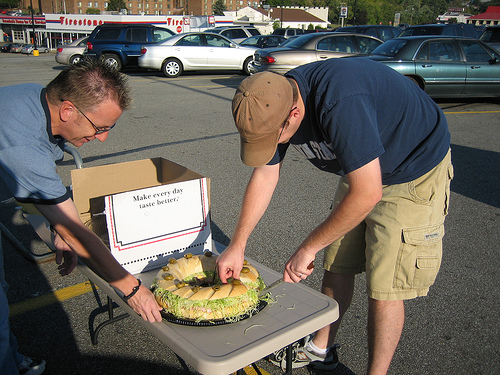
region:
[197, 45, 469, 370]
Man cutting a sandwich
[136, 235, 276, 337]
Sandwich of bread and salad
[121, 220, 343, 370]
Sandwich on a folded table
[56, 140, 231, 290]
Box of cardboard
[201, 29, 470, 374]
Man wears a blue t-shirt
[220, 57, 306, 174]
Brown cap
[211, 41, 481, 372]
Man wears tan short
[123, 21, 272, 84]
White car parking on street parking lot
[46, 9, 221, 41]
Store of Firestone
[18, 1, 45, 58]
Pole with yellow base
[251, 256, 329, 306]
knife in a persons hand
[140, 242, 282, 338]
food on a table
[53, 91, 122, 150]
glasses on a persons face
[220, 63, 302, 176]
hat on a persons head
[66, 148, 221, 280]
cardboard box on a table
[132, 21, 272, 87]
vehicle in a lot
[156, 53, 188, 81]
rear wheel of a vehicle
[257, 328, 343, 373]
shoe on a foot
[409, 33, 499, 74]
side windows on a vehicle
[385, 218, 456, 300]
pocket on a persons shorts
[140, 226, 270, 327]
A sandwich shaped like a ring.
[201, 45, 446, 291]
The man is wearing cargo shorts.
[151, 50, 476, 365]
The man is cutting the sandwich.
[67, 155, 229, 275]
A cardboard box.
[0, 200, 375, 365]
A folding table.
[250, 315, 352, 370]
A gray New Balance sneaker.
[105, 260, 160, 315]
A bracelet is on the man's arm.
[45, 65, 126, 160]
The man is wearing glasses.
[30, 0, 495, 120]
A parking lot.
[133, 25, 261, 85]
A silver car.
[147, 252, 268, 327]
Donut shaped sandwich on a black plate.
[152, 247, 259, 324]
Large wheel shaped sandwich.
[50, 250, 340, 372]
Large deli sandwich with lettuce.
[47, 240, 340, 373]
Deli sandwich on a table.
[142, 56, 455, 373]
Man cutting a large deli sandwich.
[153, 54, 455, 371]
Man standing in a parking lot cutting a large sandwich.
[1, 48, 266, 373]
Man wearing glasses in blue shirt.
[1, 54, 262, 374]
Man holding a the black tray with a large deli sandwich.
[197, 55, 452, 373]
Man wearing a brown cap.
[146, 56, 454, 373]
Man holding a knife cutting a sandwich.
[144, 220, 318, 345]
Circle sandwich.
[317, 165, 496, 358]
Cargo short.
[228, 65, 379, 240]
Man wearing a brown hat.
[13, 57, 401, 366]
Tailgating in the parking lot.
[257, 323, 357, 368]
Man wearing sneakers in the parking lot.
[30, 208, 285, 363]
Table set up in the parking lot.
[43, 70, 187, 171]
Man with glasses.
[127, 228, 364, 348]
Man cutting sandwich.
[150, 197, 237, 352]
Olives on the sandwich.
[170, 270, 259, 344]
Lettuce on the sandwich